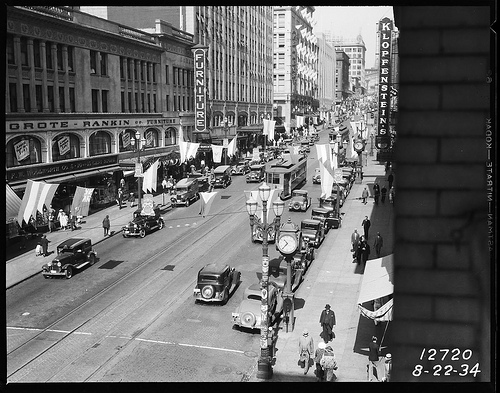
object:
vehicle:
[193, 260, 243, 310]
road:
[5, 113, 370, 385]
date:
[406, 343, 492, 382]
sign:
[15, 112, 163, 131]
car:
[40, 237, 103, 282]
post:
[248, 201, 279, 378]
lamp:
[245, 180, 287, 222]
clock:
[270, 226, 308, 254]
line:
[2, 318, 285, 359]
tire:
[61, 263, 74, 280]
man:
[318, 298, 343, 343]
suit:
[319, 311, 334, 346]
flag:
[360, 294, 397, 330]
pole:
[280, 256, 298, 334]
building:
[0, 6, 208, 233]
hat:
[325, 303, 332, 311]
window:
[83, 242, 92, 253]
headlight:
[54, 260, 63, 270]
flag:
[66, 184, 96, 220]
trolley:
[264, 147, 313, 205]